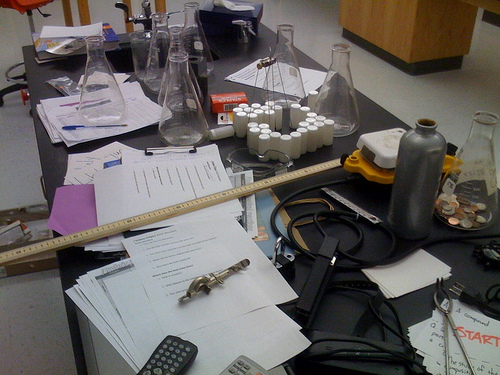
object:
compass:
[177, 258, 251, 302]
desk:
[335, 0, 478, 75]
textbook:
[32, 21, 121, 55]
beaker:
[435, 111, 499, 231]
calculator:
[135, 334, 200, 375]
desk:
[16, 0, 496, 374]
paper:
[45, 141, 258, 254]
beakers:
[78, 35, 125, 127]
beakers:
[261, 24, 307, 109]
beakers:
[312, 43, 361, 138]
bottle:
[208, 125, 235, 141]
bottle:
[307, 91, 318, 113]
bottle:
[323, 119, 335, 146]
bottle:
[257, 134, 270, 162]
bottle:
[279, 134, 292, 163]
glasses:
[225, 147, 292, 177]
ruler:
[0, 157, 342, 266]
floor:
[0, 10, 82, 368]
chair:
[0, 1, 56, 108]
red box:
[209, 92, 247, 114]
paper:
[407, 297, 499, 374]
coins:
[435, 192, 487, 229]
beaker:
[158, 51, 210, 146]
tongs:
[433, 276, 476, 374]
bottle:
[387, 118, 448, 241]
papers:
[62, 207, 312, 372]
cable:
[270, 177, 428, 374]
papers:
[361, 248, 454, 299]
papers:
[36, 81, 175, 148]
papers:
[226, 56, 338, 99]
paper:
[121, 207, 302, 338]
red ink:
[451, 325, 500, 347]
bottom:
[340, 0, 480, 77]